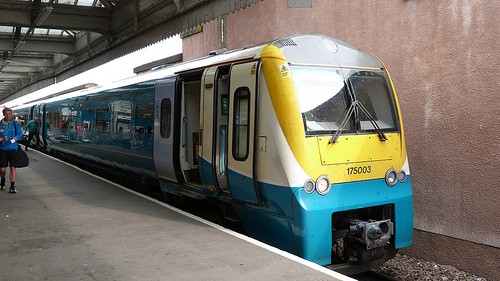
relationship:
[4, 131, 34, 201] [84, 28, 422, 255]
woman by train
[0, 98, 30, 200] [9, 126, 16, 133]
passenger in blue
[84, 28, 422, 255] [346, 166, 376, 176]
train has number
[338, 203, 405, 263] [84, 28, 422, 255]
connector on train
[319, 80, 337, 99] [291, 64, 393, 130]
light on windshield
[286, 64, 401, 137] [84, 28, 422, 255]
windshield on train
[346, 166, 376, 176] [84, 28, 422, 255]
number on train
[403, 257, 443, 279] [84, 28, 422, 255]
gravel by train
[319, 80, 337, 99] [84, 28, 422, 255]
light on train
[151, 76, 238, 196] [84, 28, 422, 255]
door on train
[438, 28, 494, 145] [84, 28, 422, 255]
wall by train